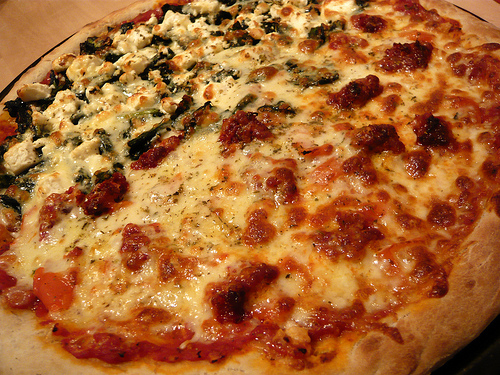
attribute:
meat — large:
[210, 104, 273, 151]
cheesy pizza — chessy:
[3, 7, 276, 177]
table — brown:
[0, 3, 75, 37]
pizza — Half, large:
[3, 0, 497, 373]